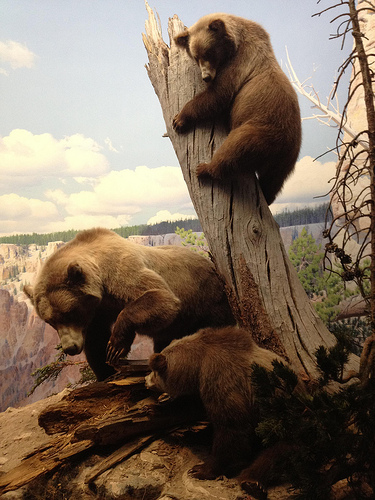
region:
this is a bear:
[184, 11, 290, 164]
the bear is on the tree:
[196, 56, 289, 182]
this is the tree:
[141, 20, 173, 59]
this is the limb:
[108, 295, 153, 352]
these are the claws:
[104, 340, 125, 361]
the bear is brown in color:
[165, 252, 192, 284]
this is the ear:
[65, 252, 88, 281]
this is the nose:
[59, 343, 79, 352]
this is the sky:
[38, 47, 124, 149]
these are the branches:
[344, 29, 373, 74]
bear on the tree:
[193, 16, 296, 224]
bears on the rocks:
[31, 210, 317, 452]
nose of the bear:
[199, 62, 221, 76]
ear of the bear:
[188, 18, 230, 34]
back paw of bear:
[187, 155, 228, 199]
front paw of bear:
[151, 96, 205, 134]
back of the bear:
[256, 32, 302, 138]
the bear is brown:
[255, 69, 290, 167]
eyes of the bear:
[177, 47, 210, 65]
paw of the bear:
[104, 321, 155, 349]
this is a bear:
[152, 332, 323, 484]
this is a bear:
[25, 226, 213, 407]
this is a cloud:
[105, 172, 158, 222]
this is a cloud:
[63, 127, 103, 190]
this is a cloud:
[113, 158, 161, 213]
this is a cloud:
[297, 152, 329, 196]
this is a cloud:
[5, 194, 51, 248]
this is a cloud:
[70, 130, 110, 170]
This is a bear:
[22, 221, 241, 358]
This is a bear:
[139, 319, 355, 496]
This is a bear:
[22, 219, 258, 367]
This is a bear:
[158, 0, 326, 231]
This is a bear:
[166, 6, 331, 232]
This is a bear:
[127, 316, 345, 498]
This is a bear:
[24, 218, 261, 361]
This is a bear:
[126, 324, 340, 495]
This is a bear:
[28, 213, 270, 365]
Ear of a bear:
[61, 263, 88, 280]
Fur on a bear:
[210, 378, 241, 410]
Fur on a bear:
[200, 352, 234, 382]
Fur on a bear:
[180, 351, 225, 386]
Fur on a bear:
[190, 348, 243, 386]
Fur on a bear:
[167, 350, 187, 378]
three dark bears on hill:
[22, 10, 303, 476]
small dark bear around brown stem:
[171, 17, 303, 209]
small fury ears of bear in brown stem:
[174, 15, 229, 49]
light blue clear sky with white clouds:
[3, 3, 371, 240]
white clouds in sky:
[0, 33, 355, 228]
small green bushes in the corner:
[243, 337, 374, 490]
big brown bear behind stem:
[18, 225, 239, 377]